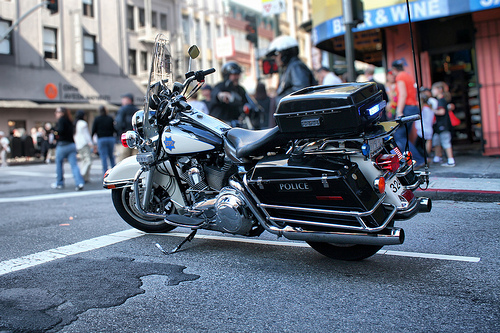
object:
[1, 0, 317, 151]
building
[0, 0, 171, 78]
windows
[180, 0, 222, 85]
windows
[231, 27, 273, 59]
windows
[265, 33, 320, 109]
man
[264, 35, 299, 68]
helmet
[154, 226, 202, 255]
kickstand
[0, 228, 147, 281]
stripe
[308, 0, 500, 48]
sign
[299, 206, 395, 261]
motorcyle tire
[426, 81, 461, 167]
child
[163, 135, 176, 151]
emblem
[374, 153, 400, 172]
light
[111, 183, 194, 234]
front wheel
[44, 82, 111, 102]
train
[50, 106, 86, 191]
person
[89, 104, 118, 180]
person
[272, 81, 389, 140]
black box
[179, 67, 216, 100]
handlebar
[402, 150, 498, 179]
sidewalk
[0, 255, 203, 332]
dark patch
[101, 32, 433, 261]
bike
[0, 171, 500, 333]
road